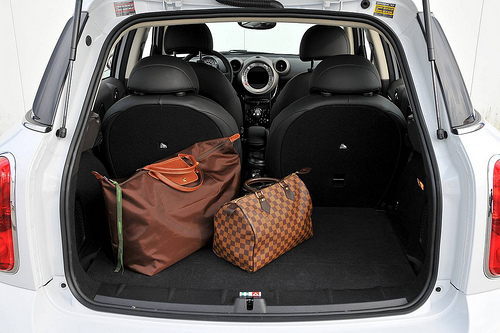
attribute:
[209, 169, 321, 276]
bag — small, brown, rust, carry on, checkered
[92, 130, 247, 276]
purse — big, dark brown, plain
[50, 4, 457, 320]
trunk — opened, open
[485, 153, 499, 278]
light — long, red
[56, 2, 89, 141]
latch — black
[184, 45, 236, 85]
steering wheel — black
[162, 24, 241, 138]
seat — driver's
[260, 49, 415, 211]
seat — leather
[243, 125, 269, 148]
gear shift — black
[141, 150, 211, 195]
handles — rust, light brown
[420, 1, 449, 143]
rod — thin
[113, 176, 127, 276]
strip — green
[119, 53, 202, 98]
headrest — gray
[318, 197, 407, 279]
floor — black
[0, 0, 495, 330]
car — white